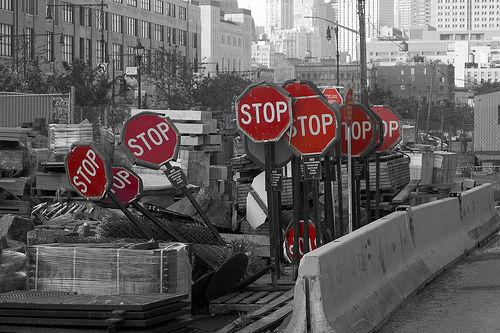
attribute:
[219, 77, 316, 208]
sign — stop, red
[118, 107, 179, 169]
stop sign — red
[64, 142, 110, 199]
sign — stop, red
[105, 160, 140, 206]
sign — red, stop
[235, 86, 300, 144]
sign — red, stop